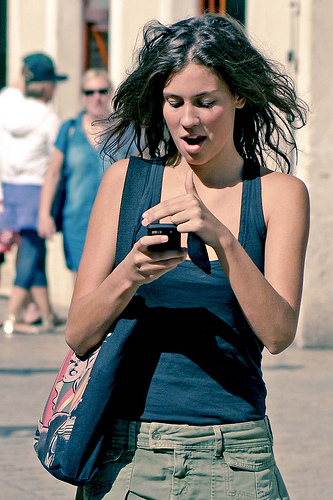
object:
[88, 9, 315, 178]
hair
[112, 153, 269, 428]
top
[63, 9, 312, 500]
girl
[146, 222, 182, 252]
phone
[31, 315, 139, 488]
bag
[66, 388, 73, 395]
drawings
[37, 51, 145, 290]
woman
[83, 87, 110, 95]
sunglasses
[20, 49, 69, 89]
cap